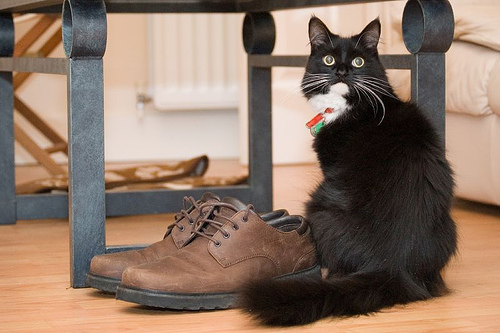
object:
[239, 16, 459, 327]
cat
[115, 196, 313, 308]
shoes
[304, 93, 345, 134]
toy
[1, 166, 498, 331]
floor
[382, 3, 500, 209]
couch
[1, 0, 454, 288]
table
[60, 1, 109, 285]
leg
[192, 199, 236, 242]
shoestring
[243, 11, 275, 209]
leg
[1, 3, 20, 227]
legs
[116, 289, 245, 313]
sole of shoe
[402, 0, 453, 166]
leg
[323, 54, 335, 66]
eye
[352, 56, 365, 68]
eye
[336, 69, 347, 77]
nose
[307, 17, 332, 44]
ear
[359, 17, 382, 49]
ear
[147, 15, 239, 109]
radiator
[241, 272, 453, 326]
tail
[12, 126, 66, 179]
legs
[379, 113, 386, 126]
whiskers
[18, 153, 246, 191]
rug